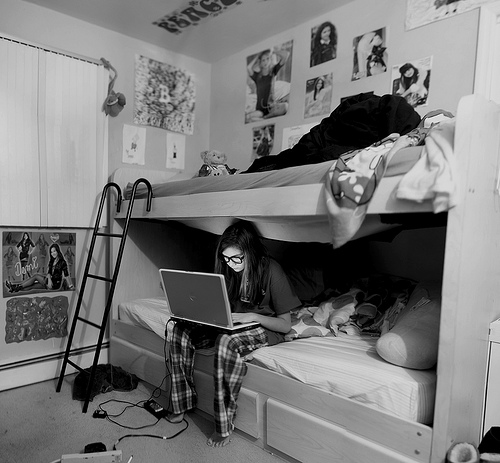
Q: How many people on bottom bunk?
A: One.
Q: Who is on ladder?
A: No one.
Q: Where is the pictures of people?
A: On wall.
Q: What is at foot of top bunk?
A: Teddy bear.